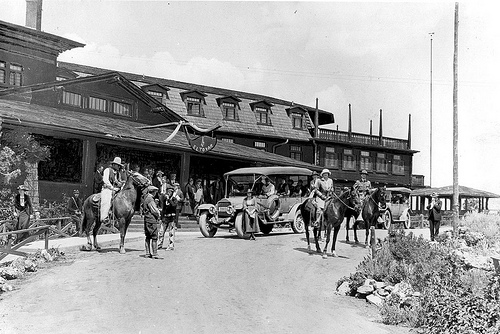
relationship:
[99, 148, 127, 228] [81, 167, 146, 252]
man riding a horse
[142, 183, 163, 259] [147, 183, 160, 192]
man in a cap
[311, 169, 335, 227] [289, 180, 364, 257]
person on a horse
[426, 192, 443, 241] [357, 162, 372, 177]
man wearing a hat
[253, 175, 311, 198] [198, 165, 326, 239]
people in a car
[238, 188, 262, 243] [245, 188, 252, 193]
person wearing a hat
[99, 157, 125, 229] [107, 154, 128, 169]
man wearing a hat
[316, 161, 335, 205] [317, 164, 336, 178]
person wearing hat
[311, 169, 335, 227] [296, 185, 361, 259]
person riding horse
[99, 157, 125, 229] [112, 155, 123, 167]
man wearing hat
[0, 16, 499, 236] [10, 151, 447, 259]
building behind people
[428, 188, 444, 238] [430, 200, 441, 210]
man wearing suit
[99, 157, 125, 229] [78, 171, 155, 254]
man riding horse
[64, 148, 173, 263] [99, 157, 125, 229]
horse with man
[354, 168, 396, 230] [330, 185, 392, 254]
person on horse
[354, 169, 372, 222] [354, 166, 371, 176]
person wearing hat